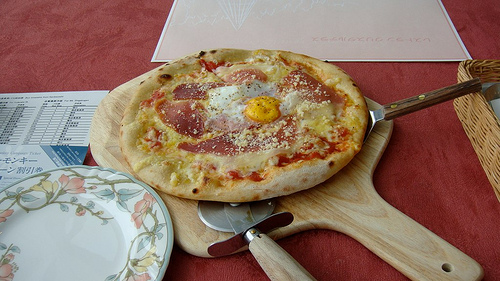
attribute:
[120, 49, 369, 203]
pizza — round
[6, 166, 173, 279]
plate — empty, white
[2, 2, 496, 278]
table — red, wood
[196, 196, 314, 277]
pizza cutter — metal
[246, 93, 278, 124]
egg yolk — cooked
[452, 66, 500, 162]
basket — wooden, wicker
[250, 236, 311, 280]
handle — wood, wooden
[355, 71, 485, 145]
pizza server — wood